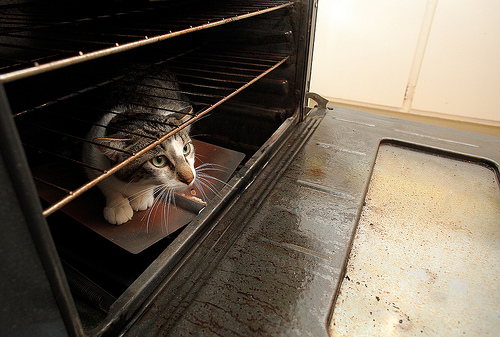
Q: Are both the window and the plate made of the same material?
A: No, the window is made of glass and the plate is made of metal.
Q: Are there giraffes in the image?
A: No, there are no giraffes.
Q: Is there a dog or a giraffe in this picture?
A: No, there are no giraffes or dogs.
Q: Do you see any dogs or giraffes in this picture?
A: No, there are no giraffes or dogs.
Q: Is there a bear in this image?
A: No, there are no bears.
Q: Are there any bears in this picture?
A: No, there are no bears.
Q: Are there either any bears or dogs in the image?
A: No, there are no bears or dogs.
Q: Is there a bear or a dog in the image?
A: No, there are no bears or dogs.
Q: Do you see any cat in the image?
A: Yes, there is a cat.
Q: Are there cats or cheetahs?
A: Yes, there is a cat.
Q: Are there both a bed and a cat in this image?
A: No, there is a cat but no beds.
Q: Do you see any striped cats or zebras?
A: Yes, there is a striped cat.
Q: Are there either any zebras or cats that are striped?
A: Yes, the cat is striped.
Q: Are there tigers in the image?
A: No, there are no tigers.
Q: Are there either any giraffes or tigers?
A: No, there are no tigers or giraffes.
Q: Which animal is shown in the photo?
A: The animal is a cat.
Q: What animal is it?
A: The animal is a cat.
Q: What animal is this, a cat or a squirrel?
A: This is a cat.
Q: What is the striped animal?
A: The animal is a cat.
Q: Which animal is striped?
A: The animal is a cat.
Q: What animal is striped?
A: The animal is a cat.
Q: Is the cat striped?
A: Yes, the cat is striped.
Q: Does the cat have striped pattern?
A: Yes, the cat is striped.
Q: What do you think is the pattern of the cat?
A: The cat is striped.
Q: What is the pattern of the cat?
A: The cat is striped.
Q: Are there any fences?
A: No, there are no fences.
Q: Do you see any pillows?
A: No, there are no pillows.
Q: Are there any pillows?
A: No, there are no pillows.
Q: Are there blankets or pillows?
A: No, there are no pillows or blankets.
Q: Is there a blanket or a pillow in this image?
A: No, there are no pillows or blankets.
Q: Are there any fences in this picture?
A: No, there are no fences.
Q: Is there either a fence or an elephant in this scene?
A: No, there are no fences or elephants.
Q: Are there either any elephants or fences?
A: No, there are no fences or elephants.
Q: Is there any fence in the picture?
A: No, there are no fences.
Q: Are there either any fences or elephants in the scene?
A: No, there are no fences or elephants.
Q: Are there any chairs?
A: No, there are no chairs.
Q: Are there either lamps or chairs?
A: No, there are no chairs or lamps.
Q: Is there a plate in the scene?
A: Yes, there is a plate.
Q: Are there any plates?
A: Yes, there is a plate.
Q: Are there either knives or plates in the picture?
A: Yes, there is a plate.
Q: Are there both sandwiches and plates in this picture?
A: No, there is a plate but no sandwiches.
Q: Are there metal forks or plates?
A: Yes, there is a metal plate.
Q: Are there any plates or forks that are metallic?
A: Yes, the plate is metallic.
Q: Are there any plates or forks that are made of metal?
A: Yes, the plate is made of metal.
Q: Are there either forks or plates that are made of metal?
A: Yes, the plate is made of metal.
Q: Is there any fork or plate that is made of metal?
A: Yes, the plate is made of metal.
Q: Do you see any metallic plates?
A: Yes, there is a metal plate.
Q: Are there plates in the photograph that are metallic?
A: Yes, there is a plate that is metallic.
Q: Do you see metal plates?
A: Yes, there is a plate that is made of metal.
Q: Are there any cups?
A: No, there are no cups.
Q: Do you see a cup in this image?
A: No, there are no cups.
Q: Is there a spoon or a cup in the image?
A: No, there are no cups or spoons.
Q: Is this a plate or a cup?
A: This is a plate.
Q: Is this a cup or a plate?
A: This is a plate.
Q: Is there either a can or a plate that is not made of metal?
A: No, there is a plate but it is made of metal.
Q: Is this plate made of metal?
A: Yes, the plate is made of metal.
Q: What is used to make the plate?
A: The plate is made of metal.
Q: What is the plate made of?
A: The plate is made of metal.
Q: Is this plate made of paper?
A: No, the plate is made of metal.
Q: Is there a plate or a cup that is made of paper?
A: No, there is a plate but it is made of metal.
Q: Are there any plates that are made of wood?
A: No, there is a plate but it is made of metal.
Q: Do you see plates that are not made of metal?
A: No, there is a plate but it is made of metal.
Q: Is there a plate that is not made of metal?
A: No, there is a plate but it is made of metal.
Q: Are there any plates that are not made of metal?
A: No, there is a plate but it is made of metal.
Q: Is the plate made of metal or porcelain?
A: The plate is made of metal.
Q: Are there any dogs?
A: No, there are no dogs.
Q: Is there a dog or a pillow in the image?
A: No, there are no dogs or pillows.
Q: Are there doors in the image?
A: Yes, there is a door.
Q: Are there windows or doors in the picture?
A: Yes, there is a door.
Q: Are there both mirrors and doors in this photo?
A: No, there is a door but no mirrors.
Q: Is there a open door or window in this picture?
A: Yes, there is an open door.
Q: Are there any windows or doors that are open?
A: Yes, the door is open.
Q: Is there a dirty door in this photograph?
A: Yes, there is a dirty door.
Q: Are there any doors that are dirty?
A: Yes, there is a door that is dirty.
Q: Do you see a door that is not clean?
A: Yes, there is a dirty door.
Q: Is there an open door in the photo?
A: Yes, there is an open door.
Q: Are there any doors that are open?
A: Yes, there is a door that is open.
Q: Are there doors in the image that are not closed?
A: Yes, there is a open door.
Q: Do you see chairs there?
A: No, there are no chairs.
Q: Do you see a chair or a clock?
A: No, there are no chairs or clocks.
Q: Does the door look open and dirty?
A: Yes, the door is open and dirty.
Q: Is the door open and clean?
A: No, the door is open but dirty.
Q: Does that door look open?
A: Yes, the door is open.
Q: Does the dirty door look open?
A: Yes, the door is open.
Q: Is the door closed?
A: No, the door is open.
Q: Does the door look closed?
A: No, the door is open.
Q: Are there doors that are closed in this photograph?
A: No, there is a door but it is open.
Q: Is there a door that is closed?
A: No, there is a door but it is open.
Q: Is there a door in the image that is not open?
A: No, there is a door but it is open.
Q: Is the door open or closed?
A: The door is open.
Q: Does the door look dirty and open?
A: Yes, the door is dirty and open.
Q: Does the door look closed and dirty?
A: No, the door is dirty but open.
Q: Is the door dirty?
A: Yes, the door is dirty.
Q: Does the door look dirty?
A: Yes, the door is dirty.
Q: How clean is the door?
A: The door is dirty.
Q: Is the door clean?
A: No, the door is dirty.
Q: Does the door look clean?
A: No, the door is dirty.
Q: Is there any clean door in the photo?
A: No, there is a door but it is dirty.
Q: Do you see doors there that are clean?
A: No, there is a door but it is dirty.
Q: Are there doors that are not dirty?
A: No, there is a door but it is dirty.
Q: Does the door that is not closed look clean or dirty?
A: The door is dirty.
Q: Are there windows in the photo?
A: Yes, there is a window.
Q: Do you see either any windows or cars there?
A: Yes, there is a window.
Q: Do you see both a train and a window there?
A: No, there is a window but no trains.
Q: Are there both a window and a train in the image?
A: No, there is a window but no trains.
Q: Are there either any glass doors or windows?
A: Yes, there is a glass window.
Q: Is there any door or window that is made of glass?
A: Yes, the window is made of glass.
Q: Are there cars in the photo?
A: No, there are no cars.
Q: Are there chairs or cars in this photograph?
A: No, there are no cars or chairs.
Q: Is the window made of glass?
A: Yes, the window is made of glass.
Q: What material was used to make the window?
A: The window is made of glass.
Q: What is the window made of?
A: The window is made of glass.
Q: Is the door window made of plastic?
A: No, the window is made of glass.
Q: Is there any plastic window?
A: No, there is a window but it is made of glass.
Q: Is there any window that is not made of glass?
A: No, there is a window but it is made of glass.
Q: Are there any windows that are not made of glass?
A: No, there is a window but it is made of glass.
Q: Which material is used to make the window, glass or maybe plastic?
A: The window is made of glass.